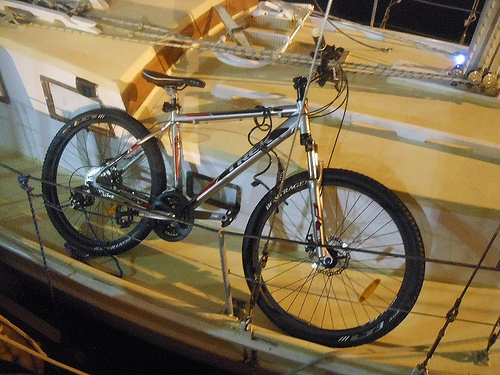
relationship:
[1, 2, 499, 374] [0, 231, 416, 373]
boat has edge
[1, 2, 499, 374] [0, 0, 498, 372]
boat has surface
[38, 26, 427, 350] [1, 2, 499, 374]
bike on boat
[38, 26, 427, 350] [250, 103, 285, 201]
bike has lock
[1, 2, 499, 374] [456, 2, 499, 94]
boat has mast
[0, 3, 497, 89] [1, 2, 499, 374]
rope on boat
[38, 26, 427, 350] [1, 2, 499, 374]
bike sitting on boat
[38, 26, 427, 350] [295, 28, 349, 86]
bike has steering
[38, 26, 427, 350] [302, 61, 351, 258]
bike has brake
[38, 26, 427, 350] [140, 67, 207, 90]
bike has seat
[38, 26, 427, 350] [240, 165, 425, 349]
bike has wheel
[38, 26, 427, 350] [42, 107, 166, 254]
bike has wheel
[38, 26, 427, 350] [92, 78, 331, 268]
bike has frame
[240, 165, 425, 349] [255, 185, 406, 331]
wheel has spokes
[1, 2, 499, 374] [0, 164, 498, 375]
boat has cables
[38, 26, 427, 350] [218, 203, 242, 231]
bike has pedal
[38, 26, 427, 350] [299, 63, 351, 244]
bike has cables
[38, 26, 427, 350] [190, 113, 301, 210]
bike has rod